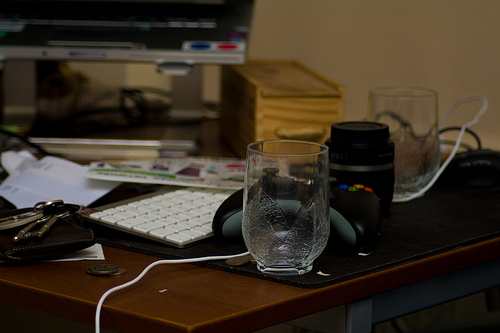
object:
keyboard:
[77, 186, 234, 255]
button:
[348, 186, 358, 191]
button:
[362, 185, 374, 192]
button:
[340, 184, 350, 189]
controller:
[209, 170, 382, 261]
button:
[354, 183, 366, 189]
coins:
[89, 263, 118, 273]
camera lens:
[323, 120, 398, 216]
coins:
[81, 263, 126, 277]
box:
[220, 58, 346, 156]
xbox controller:
[209, 166, 387, 245]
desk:
[1, 218, 494, 328]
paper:
[88, 156, 253, 189]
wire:
[92, 94, 491, 331]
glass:
[367, 83, 442, 204]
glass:
[239, 137, 330, 277]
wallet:
[5, 209, 97, 262]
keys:
[0, 199, 79, 239]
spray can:
[318, 120, 396, 200]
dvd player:
[29, 102, 173, 150]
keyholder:
[33, 201, 47, 212]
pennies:
[84, 263, 125, 278]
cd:
[88, 155, 243, 189]